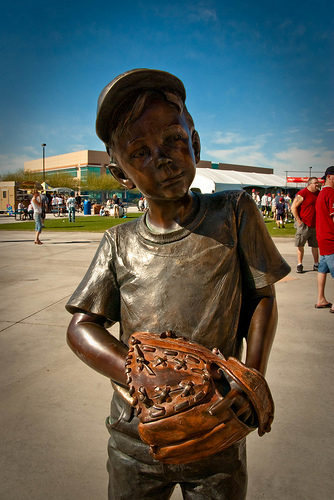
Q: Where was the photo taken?
A: It was taken at the field.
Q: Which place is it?
A: It is a field.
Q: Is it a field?
A: Yes, it is a field.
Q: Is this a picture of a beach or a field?
A: It is showing a field.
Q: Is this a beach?
A: No, it is a field.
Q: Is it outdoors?
A: Yes, it is outdoors.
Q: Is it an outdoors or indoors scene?
A: It is outdoors.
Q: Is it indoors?
A: No, it is outdoors.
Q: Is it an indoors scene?
A: No, it is outdoors.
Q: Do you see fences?
A: No, there are no fences.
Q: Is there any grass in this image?
A: Yes, there is grass.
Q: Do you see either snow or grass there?
A: Yes, there is grass.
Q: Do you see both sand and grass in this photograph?
A: No, there is grass but no sand.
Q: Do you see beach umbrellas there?
A: No, there are no beach umbrellas.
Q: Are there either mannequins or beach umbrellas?
A: No, there are no beach umbrellas or mannequins.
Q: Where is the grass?
A: The grass is in the field.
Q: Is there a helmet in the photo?
A: No, there are no helmets.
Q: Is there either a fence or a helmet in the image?
A: No, there are no helmets or fences.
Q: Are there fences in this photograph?
A: No, there are no fences.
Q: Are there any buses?
A: No, there are no buses.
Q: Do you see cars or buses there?
A: No, there are no buses or cars.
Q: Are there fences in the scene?
A: No, there are no fences.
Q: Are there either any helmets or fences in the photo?
A: No, there are no fences or helmets.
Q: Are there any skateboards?
A: No, there are no skateboards.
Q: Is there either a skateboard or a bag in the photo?
A: No, there are no skateboards or bags.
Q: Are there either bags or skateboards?
A: No, there are no skateboards or bags.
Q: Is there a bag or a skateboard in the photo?
A: No, there are no skateboards or bags.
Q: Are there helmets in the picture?
A: No, there are no helmets.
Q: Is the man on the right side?
A: Yes, the man is on the right of the image.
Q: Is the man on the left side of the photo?
A: No, the man is on the right of the image.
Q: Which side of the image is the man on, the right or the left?
A: The man is on the right of the image.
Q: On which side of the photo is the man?
A: The man is on the right of the image.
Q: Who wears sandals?
A: The man wears sandals.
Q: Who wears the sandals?
A: The man wears sandals.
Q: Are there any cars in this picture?
A: No, there are no cars.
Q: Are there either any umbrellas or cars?
A: No, there are no cars or umbrellas.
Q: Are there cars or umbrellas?
A: No, there are no cars or umbrellas.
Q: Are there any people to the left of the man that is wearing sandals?
A: Yes, there are people to the left of the man.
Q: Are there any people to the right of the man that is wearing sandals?
A: No, the people are to the left of the man.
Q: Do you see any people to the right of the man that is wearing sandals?
A: No, the people are to the left of the man.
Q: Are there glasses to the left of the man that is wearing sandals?
A: No, there are people to the left of the man.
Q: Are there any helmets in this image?
A: No, there are no helmets.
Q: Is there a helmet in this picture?
A: No, there are no helmets.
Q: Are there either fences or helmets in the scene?
A: No, there are no helmets or fences.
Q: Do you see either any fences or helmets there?
A: No, there are no helmets or fences.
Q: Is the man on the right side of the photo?
A: Yes, the man is on the right of the image.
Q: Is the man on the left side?
A: No, the man is on the right of the image.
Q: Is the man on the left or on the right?
A: The man is on the right of the image.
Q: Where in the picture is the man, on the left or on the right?
A: The man is on the right of the image.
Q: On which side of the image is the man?
A: The man is on the right of the image.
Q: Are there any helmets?
A: No, there are no helmets.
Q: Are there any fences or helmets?
A: No, there are no helmets or fences.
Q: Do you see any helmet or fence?
A: No, there are no helmets or fences.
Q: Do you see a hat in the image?
A: Yes, there is a hat.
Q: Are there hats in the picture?
A: Yes, there is a hat.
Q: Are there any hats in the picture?
A: Yes, there is a hat.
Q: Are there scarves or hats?
A: Yes, there is a hat.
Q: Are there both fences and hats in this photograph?
A: No, there is a hat but no fences.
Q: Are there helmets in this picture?
A: No, there are no helmets.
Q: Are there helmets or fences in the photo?
A: No, there are no helmets or fences.